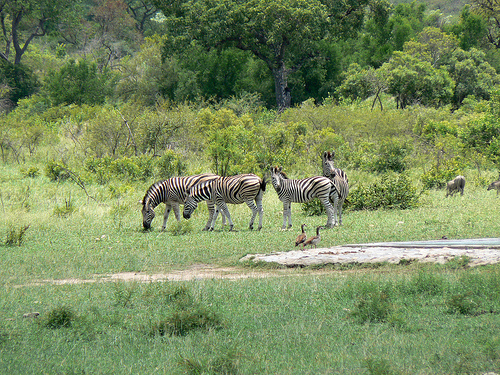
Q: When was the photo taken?
A: Daytime.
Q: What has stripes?
A: Zebra.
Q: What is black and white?
A: The zebra.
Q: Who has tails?
A: Four Zebra.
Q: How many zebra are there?
A: Four.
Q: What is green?
A: Grass.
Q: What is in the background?
A: Trees.